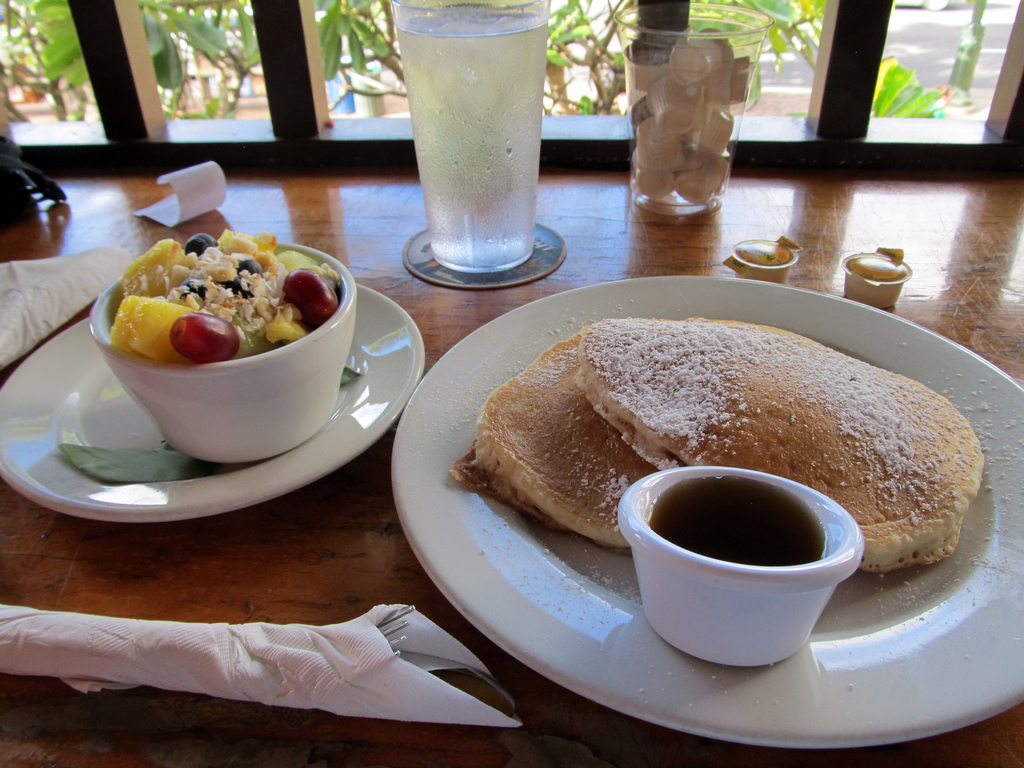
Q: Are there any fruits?
A: Yes, there is a fruit.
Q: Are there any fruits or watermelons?
A: Yes, there is a fruit.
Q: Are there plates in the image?
A: Yes, there is a plate.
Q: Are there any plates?
A: Yes, there is a plate.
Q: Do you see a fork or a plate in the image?
A: Yes, there is a plate.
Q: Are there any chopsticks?
A: No, there are no chopsticks.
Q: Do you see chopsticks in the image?
A: No, there are no chopsticks.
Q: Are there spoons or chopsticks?
A: No, there are no chopsticks or spoons.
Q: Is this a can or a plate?
A: This is a plate.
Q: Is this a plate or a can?
A: This is a plate.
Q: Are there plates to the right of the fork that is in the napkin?
A: Yes, there is a plate to the right of the fork.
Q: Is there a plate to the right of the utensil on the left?
A: Yes, there is a plate to the right of the fork.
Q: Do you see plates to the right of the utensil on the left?
A: Yes, there is a plate to the right of the fork.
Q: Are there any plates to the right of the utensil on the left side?
A: Yes, there is a plate to the right of the fork.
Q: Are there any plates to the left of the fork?
A: No, the plate is to the right of the fork.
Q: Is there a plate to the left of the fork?
A: No, the plate is to the right of the fork.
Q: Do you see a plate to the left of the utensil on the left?
A: No, the plate is to the right of the fork.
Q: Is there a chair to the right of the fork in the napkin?
A: No, there is a plate to the right of the fork.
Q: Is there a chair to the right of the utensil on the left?
A: No, there is a plate to the right of the fork.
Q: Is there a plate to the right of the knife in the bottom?
A: Yes, there is a plate to the right of the knife.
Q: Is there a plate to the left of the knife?
A: No, the plate is to the right of the knife.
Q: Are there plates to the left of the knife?
A: No, the plate is to the right of the knife.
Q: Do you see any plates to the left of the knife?
A: No, the plate is to the right of the knife.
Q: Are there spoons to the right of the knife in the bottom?
A: No, there is a plate to the right of the knife.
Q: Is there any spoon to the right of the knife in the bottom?
A: No, there is a plate to the right of the knife.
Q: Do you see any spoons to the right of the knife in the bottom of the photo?
A: No, there is a plate to the right of the knife.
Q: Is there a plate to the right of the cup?
A: Yes, there is a plate to the right of the cup.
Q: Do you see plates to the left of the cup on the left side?
A: No, the plate is to the right of the cup.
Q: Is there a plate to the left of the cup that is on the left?
A: No, the plate is to the right of the cup.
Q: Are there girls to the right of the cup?
A: No, there is a plate to the right of the cup.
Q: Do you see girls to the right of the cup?
A: No, there is a plate to the right of the cup.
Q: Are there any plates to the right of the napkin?
A: Yes, there is a plate to the right of the napkin.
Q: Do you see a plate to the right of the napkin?
A: Yes, there is a plate to the right of the napkin.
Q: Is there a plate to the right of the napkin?
A: Yes, there is a plate to the right of the napkin.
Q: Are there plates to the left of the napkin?
A: No, the plate is to the right of the napkin.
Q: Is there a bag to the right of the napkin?
A: No, there is a plate to the right of the napkin.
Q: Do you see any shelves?
A: No, there are no shelves.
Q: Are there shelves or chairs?
A: No, there are no shelves or chairs.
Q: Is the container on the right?
A: Yes, the container is on the right of the image.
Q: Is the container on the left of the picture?
A: No, the container is on the right of the image.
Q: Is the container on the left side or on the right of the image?
A: The container is on the right of the image.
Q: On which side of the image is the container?
A: The container is on the right of the image.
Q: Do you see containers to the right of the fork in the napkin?
A: Yes, there is a container to the right of the fork.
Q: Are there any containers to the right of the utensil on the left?
A: Yes, there is a container to the right of the fork.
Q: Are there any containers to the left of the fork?
A: No, the container is to the right of the fork.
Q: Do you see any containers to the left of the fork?
A: No, the container is to the right of the fork.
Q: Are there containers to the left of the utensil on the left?
A: No, the container is to the right of the fork.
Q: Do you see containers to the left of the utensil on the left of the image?
A: No, the container is to the right of the fork.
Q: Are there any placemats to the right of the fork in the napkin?
A: No, there is a container to the right of the fork.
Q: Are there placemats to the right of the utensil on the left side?
A: No, there is a container to the right of the fork.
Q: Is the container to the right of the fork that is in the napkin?
A: Yes, the container is to the right of the fork.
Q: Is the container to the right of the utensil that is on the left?
A: Yes, the container is to the right of the fork.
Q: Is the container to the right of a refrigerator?
A: No, the container is to the right of the fork.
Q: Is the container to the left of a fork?
A: No, the container is to the right of a fork.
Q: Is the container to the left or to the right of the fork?
A: The container is to the right of the fork.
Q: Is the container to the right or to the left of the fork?
A: The container is to the right of the fork.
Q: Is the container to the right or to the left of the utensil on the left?
A: The container is to the right of the fork.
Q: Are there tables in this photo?
A: Yes, there is a table.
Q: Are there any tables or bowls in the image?
A: Yes, there is a table.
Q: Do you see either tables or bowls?
A: Yes, there is a table.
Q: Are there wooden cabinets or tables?
A: Yes, there is a wood table.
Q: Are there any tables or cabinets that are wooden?
A: Yes, the table is wooden.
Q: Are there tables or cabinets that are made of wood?
A: Yes, the table is made of wood.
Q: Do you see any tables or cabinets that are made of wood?
A: Yes, the table is made of wood.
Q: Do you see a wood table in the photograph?
A: Yes, there is a wood table.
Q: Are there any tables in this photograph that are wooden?
A: Yes, there is a table that is wooden.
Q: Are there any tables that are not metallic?
A: Yes, there is a wooden table.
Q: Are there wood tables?
A: Yes, there is a table that is made of wood.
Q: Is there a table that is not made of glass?
A: Yes, there is a table that is made of wood.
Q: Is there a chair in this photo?
A: No, there are no chairs.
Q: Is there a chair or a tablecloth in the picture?
A: No, there are no chairs or tablecloths.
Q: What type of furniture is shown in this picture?
A: The furniture is a table.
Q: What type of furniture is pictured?
A: The furniture is a table.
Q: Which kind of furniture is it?
A: The piece of furniture is a table.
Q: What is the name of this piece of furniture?
A: This is a table.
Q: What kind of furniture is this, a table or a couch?
A: This is a table.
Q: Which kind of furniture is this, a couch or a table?
A: This is a table.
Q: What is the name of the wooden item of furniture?
A: The piece of furniture is a table.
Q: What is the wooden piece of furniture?
A: The piece of furniture is a table.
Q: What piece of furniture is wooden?
A: The piece of furniture is a table.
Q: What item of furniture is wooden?
A: The piece of furniture is a table.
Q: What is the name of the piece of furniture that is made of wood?
A: The piece of furniture is a table.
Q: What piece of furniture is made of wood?
A: The piece of furniture is a table.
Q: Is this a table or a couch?
A: This is a table.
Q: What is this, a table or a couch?
A: This is a table.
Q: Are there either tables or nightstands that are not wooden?
A: No, there is a table but it is wooden.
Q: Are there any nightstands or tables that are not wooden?
A: No, there is a table but it is wooden.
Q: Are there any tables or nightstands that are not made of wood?
A: No, there is a table but it is made of wood.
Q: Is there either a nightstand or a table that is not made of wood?
A: No, there is a table but it is made of wood.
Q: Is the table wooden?
A: Yes, the table is wooden.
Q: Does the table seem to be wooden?
A: Yes, the table is wooden.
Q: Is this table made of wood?
A: Yes, the table is made of wood.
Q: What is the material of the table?
A: The table is made of wood.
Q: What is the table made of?
A: The table is made of wood.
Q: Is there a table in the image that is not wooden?
A: No, there is a table but it is wooden.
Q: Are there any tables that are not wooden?
A: No, there is a table but it is wooden.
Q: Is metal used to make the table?
A: No, the table is made of wood.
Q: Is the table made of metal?
A: No, the table is made of wood.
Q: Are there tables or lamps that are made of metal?
A: No, there is a table but it is made of wood.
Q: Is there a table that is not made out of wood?
A: No, there is a table but it is made of wood.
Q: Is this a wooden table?
A: Yes, this is a wooden table.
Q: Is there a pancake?
A: Yes, there are pancakes.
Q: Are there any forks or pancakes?
A: Yes, there are pancakes.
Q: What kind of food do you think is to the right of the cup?
A: The food is pancakes.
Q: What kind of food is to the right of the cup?
A: The food is pancakes.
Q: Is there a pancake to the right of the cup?
A: Yes, there are pancakes to the right of the cup.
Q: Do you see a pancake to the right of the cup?
A: Yes, there are pancakes to the right of the cup.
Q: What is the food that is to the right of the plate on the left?
A: The food is pancakes.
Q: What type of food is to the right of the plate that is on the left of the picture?
A: The food is pancakes.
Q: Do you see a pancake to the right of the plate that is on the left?
A: Yes, there are pancakes to the right of the plate.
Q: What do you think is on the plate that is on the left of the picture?
A: The pancakes are on the plate.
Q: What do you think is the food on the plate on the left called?
A: The food is pancakes.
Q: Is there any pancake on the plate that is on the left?
A: Yes, there are pancakes on the plate.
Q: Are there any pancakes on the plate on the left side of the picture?
A: Yes, there are pancakes on the plate.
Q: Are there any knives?
A: Yes, there is a knife.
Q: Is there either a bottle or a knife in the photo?
A: Yes, there is a knife.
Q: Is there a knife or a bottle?
A: Yes, there is a knife.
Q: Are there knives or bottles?
A: Yes, there is a knife.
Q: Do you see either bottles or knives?
A: Yes, there is a knife.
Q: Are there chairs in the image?
A: No, there are no chairs.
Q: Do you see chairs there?
A: No, there are no chairs.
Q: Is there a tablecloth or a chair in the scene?
A: No, there are no chairs or tablecloths.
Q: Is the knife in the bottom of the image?
A: Yes, the knife is in the bottom of the image.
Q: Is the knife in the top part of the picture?
A: No, the knife is in the bottom of the image.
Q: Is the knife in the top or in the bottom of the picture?
A: The knife is in the bottom of the image.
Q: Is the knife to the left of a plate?
A: Yes, the knife is to the left of a plate.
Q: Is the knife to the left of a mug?
A: No, the knife is to the left of a plate.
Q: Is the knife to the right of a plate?
A: No, the knife is to the left of a plate.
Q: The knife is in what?
A: The knife is in the napkin.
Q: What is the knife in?
A: The knife is in the napkin.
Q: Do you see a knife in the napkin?
A: Yes, there is a knife in the napkin.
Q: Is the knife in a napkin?
A: Yes, the knife is in a napkin.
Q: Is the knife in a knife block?
A: No, the knife is in a napkin.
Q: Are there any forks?
A: Yes, there is a fork.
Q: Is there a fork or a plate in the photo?
A: Yes, there is a fork.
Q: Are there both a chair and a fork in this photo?
A: No, there is a fork but no chairs.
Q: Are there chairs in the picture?
A: No, there are no chairs.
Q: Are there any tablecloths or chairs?
A: No, there are no chairs or tablecloths.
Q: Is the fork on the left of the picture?
A: Yes, the fork is on the left of the image.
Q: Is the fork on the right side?
A: No, the fork is on the left of the image.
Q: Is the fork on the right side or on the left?
A: The fork is on the left of the image.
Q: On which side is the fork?
A: The fork is on the left of the image.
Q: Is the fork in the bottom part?
A: Yes, the fork is in the bottom of the image.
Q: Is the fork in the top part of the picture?
A: No, the fork is in the bottom of the image.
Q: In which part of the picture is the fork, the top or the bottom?
A: The fork is in the bottom of the image.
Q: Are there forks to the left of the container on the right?
A: Yes, there is a fork to the left of the container.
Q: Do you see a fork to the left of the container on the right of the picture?
A: Yes, there is a fork to the left of the container.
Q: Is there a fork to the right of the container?
A: No, the fork is to the left of the container.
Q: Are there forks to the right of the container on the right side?
A: No, the fork is to the left of the container.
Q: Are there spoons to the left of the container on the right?
A: No, there is a fork to the left of the container.